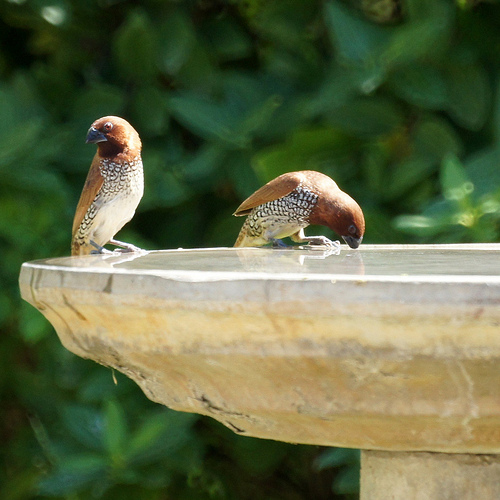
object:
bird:
[226, 168, 368, 253]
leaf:
[374, 1, 456, 73]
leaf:
[387, 60, 448, 106]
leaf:
[438, 44, 492, 131]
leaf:
[441, 156, 473, 212]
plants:
[0, 0, 499, 499]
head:
[80, 109, 145, 163]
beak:
[79, 121, 111, 148]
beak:
[335, 231, 368, 255]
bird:
[70, 112, 144, 256]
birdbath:
[14, 240, 500, 452]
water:
[112, 245, 500, 275]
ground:
[316, 93, 363, 115]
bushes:
[238, 5, 441, 139]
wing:
[234, 167, 323, 215]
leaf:
[168, 97, 252, 151]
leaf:
[155, 6, 193, 76]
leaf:
[237, 3, 328, 68]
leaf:
[110, 10, 163, 87]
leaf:
[66, 88, 124, 126]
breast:
[99, 165, 145, 236]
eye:
[341, 221, 362, 236]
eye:
[100, 120, 112, 133]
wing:
[64, 148, 104, 240]